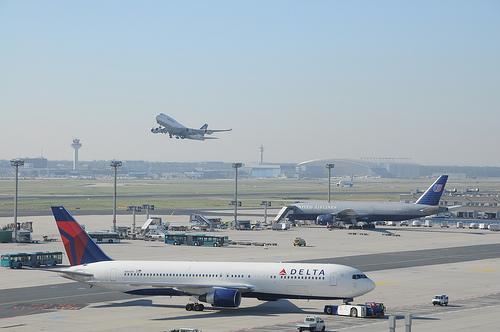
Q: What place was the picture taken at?
A: It was taken at the airport.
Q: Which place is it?
A: It is an airport.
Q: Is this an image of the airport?
A: Yes, it is showing the airport.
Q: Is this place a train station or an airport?
A: It is an airport.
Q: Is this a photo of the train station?
A: No, the picture is showing the airport.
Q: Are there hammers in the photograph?
A: No, there are no hammers.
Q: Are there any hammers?
A: No, there are no hammers.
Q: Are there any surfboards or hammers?
A: No, there are no hammers or surfboards.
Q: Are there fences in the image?
A: No, there are no fences.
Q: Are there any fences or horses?
A: No, there are no fences or horses.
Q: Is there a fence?
A: No, there are no fences.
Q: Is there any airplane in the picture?
A: Yes, there is an airplane.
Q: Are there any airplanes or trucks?
A: Yes, there is an airplane.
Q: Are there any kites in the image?
A: No, there are no kites.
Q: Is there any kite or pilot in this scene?
A: No, there are no kites or pilots.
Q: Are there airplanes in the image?
A: Yes, there is an airplane.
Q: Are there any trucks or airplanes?
A: Yes, there is an airplane.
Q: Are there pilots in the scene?
A: No, there are no pilots.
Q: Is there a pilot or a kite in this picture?
A: No, there are no pilots or kites.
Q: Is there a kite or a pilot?
A: No, there are no pilots or kites.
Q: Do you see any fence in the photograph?
A: No, there are no fences.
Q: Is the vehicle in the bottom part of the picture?
A: Yes, the vehicle is in the bottom of the image.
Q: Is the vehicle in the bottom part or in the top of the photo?
A: The vehicle is in the bottom of the image.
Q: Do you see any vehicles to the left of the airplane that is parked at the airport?
A: Yes, there is a vehicle to the left of the plane.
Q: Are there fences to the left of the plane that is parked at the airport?
A: No, there is a vehicle to the left of the plane.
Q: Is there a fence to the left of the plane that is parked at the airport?
A: No, there is a vehicle to the left of the plane.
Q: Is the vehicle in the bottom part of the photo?
A: Yes, the vehicle is in the bottom of the image.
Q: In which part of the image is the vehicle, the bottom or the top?
A: The vehicle is in the bottom of the image.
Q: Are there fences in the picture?
A: No, there are no fences.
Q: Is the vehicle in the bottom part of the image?
A: Yes, the vehicle is in the bottom of the image.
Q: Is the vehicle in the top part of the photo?
A: No, the vehicle is in the bottom of the image.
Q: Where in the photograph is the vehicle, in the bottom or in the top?
A: The vehicle is in the bottom of the image.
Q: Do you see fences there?
A: No, there are no fences.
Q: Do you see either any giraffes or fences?
A: No, there are no fences or giraffes.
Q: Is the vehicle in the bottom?
A: Yes, the vehicle is in the bottom of the image.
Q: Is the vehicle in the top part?
A: No, the vehicle is in the bottom of the image.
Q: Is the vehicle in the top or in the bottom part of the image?
A: The vehicle is in the bottom of the image.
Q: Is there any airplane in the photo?
A: Yes, there is an airplane.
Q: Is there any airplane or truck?
A: Yes, there is an airplane.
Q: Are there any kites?
A: No, there are no kites.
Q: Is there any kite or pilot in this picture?
A: No, there are no kites or pilots.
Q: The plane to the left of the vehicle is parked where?
A: The plane is parked at the airport.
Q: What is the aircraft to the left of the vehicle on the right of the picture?
A: The aircraft is an airplane.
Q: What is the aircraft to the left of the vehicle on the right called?
A: The aircraft is an airplane.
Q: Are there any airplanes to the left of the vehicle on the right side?
A: Yes, there is an airplane to the left of the vehicle.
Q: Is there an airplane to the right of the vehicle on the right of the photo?
A: No, the airplane is to the left of the vehicle.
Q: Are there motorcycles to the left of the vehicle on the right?
A: No, there is an airplane to the left of the vehicle.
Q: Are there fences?
A: No, there are no fences.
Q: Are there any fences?
A: No, there are no fences.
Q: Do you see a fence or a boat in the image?
A: No, there are no fences or boats.